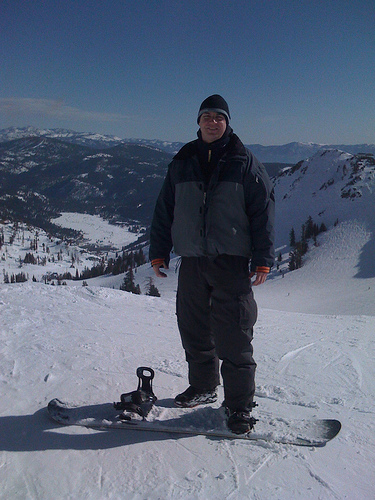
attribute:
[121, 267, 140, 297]
green tree — in background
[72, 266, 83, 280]
green tree — in background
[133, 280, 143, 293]
green tree — in background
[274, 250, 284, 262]
green tree — in background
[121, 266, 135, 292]
green tree — in background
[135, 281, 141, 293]
green tree — in background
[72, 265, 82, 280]
green tree — in background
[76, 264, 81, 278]
green tree — in background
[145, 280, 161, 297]
green tree — in background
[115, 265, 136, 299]
green tree — in background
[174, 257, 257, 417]
snow pants — black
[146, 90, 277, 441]
man — on top of mountain, grey and black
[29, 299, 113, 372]
snow — on a hill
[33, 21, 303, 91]
blue sky — over the mountains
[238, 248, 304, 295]
cuff — orange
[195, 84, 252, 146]
cap — black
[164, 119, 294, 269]
coat — black, grey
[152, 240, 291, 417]
pants — black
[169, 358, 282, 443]
boots — black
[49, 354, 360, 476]
ski — white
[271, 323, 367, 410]
snow — white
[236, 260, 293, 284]
cuffs — orange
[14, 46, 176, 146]
sky — white, blue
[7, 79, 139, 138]
clouds — white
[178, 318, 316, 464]
boots — black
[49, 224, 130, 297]
trees — ever green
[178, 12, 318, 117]
sky — dim blue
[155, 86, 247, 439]
man — standing, smiling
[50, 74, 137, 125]
clouds — white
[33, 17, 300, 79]
sky — blue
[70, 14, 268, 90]
sky — blue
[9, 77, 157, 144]
clouds — white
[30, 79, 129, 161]
clouds — white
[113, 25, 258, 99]
sky — blue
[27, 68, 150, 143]
clouds — white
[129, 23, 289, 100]
sky — blue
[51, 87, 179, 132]
sky — blue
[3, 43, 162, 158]
clouds — white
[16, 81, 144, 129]
clouds — white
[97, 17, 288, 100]
sky — blue